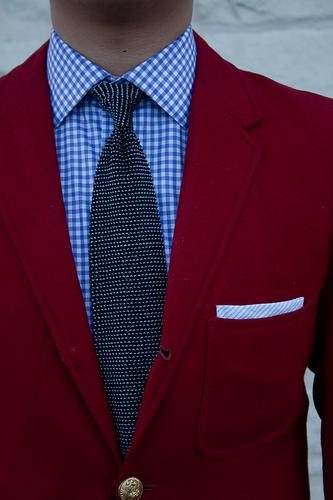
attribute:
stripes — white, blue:
[213, 296, 305, 317]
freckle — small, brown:
[122, 49, 125, 52]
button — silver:
[111, 436, 158, 498]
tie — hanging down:
[86, 76, 174, 457]